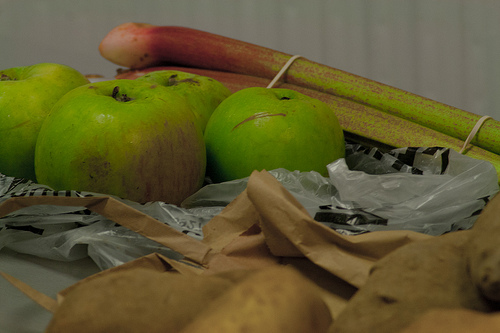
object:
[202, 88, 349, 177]
apple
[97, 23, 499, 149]
fruit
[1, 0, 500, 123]
wall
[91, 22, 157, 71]
end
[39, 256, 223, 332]
potato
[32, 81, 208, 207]
apple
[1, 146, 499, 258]
bags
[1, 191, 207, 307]
handle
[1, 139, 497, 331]
table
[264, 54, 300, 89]
rubber band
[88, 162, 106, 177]
spot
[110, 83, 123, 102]
stem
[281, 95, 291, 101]
stem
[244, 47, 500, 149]
stalk